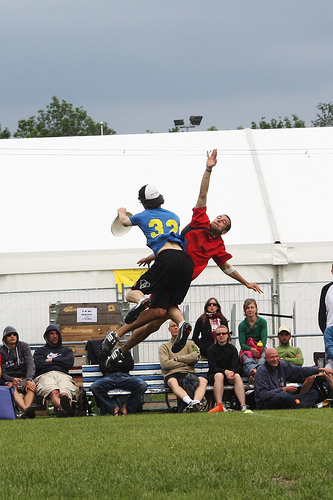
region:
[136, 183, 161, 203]
Person wearing black and white hat.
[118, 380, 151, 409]
Person wearing blue jeans.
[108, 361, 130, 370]
Person wearing black shirt.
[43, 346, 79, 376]
Person wearing black hoodie.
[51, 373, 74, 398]
Person wearing khaki shorts.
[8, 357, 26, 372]
Person wearing gray sweatshirt.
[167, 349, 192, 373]
Person wearing tan sweater.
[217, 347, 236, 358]
Person wearing black shirt.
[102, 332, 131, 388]
Person wearing black and white shoes.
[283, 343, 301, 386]
Person wearing green shirt.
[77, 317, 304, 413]
four spectators sitting on a bench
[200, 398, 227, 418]
orange cone laying on it's side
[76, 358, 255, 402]
blue and white bench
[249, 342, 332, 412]
man sitting on the ground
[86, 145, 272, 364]
two men in the air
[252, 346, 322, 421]
bald man sitting on the grass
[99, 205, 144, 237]
white Frisbee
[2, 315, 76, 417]
two men wearing gray hoodies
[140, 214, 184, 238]
man wearing a blue shirt with the number 32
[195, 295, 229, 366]
woman standing wearing sunglasses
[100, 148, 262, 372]
two Frisbee players jumping in the air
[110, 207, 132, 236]
a white Frisbee in the man's hand wearing a blue jersey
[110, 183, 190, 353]
Frisbee player in a blue jersey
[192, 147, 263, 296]
Frisbee player wearing a red jersey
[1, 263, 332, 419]
spectators watching the men play a game of Frisbee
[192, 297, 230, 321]
a female spectator wearing sunglasses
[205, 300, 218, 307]
black sunglasses over the woman's eyes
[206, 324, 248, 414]
a woman sitting on a blue and white bench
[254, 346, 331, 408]
a bald man sitting on the ground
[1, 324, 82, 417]
two men wearing hoods of a sweatshirt on the heads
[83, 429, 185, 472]
patch of green grass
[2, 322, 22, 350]
man in hoodie wearing glasses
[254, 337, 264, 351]
yellow top of water bottle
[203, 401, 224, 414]
orange cone laying on side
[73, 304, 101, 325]
white sign with black lettering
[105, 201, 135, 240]
white frisbee being held in hand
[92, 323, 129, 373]
black shoes with white stripes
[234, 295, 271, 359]
woman wearing green shirt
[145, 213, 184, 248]
the number 32 in yellow writing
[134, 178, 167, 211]
black and white baseball cap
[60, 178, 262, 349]
the people are in the air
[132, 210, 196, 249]
the shirt is blue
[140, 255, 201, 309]
the sshort is black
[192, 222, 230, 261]
the top is red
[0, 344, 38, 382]
th jamper is grey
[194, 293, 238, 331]
the woman has sunglasses on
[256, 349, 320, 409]
the guy is bald headed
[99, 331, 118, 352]
the shoes are striped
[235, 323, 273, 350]
the shirt is green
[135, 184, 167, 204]
the cap is black and white